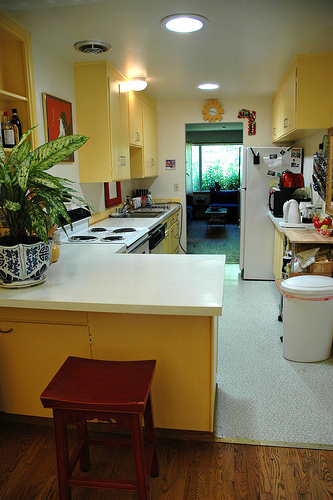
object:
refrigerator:
[238, 145, 303, 280]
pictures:
[269, 154, 277, 159]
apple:
[312, 216, 331, 229]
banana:
[321, 224, 330, 236]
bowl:
[315, 227, 331, 235]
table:
[205, 204, 230, 238]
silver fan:
[73, 39, 111, 55]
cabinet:
[271, 62, 333, 147]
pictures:
[252, 152, 262, 166]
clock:
[201, 97, 225, 123]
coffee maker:
[282, 171, 304, 187]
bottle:
[1, 111, 19, 148]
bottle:
[10, 109, 22, 145]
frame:
[42, 91, 76, 164]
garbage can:
[280, 274, 333, 363]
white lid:
[280, 274, 333, 298]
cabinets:
[74, 60, 158, 184]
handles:
[118, 154, 127, 166]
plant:
[0, 125, 96, 246]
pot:
[0, 239, 51, 290]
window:
[185, 142, 244, 190]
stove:
[61, 203, 181, 255]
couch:
[209, 190, 239, 218]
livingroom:
[188, 137, 239, 254]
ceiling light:
[165, 16, 204, 34]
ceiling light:
[128, 79, 148, 91]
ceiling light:
[197, 83, 220, 90]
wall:
[33, 44, 133, 217]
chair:
[40, 355, 156, 499]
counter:
[0, 242, 226, 431]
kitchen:
[1, 0, 332, 497]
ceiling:
[0, 0, 332, 98]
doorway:
[185, 122, 241, 264]